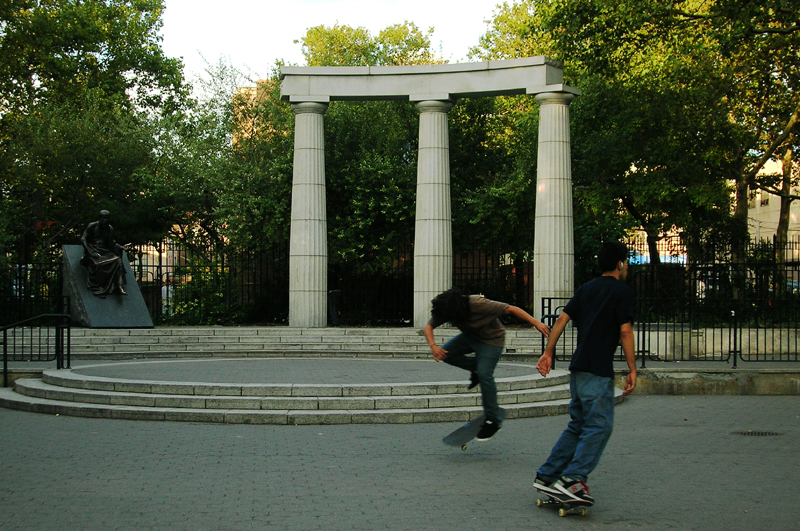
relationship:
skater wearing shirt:
[423, 288, 553, 445] [428, 295, 510, 351]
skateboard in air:
[443, 408, 511, 453] [376, 368, 581, 465]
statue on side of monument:
[78, 205, 130, 303] [48, 240, 154, 327]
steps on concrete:
[10, 357, 622, 407] [0, 396, 769, 529]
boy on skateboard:
[423, 286, 545, 441] [443, 408, 505, 451]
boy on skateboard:
[541, 242, 638, 500] [535, 486, 597, 520]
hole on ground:
[733, 425, 789, 442] [8, 387, 792, 529]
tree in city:
[6, 3, 232, 314] [6, 4, 794, 526]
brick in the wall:
[318, 324, 335, 342] [204, 317, 384, 357]